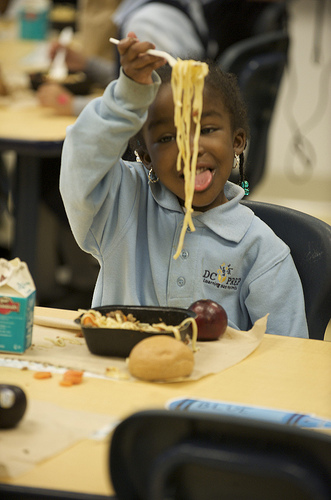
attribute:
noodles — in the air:
[165, 58, 212, 263]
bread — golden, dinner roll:
[123, 331, 200, 385]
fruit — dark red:
[187, 297, 228, 342]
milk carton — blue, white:
[1, 256, 38, 359]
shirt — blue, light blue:
[53, 60, 308, 342]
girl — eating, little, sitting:
[53, 34, 311, 342]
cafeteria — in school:
[2, 3, 328, 499]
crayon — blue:
[164, 398, 329, 435]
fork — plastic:
[109, 36, 209, 79]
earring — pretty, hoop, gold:
[144, 165, 162, 188]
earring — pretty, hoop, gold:
[228, 155, 241, 172]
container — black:
[70, 301, 198, 362]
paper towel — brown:
[3, 304, 271, 389]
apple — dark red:
[183, 295, 230, 342]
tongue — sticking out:
[190, 170, 215, 193]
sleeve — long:
[46, 66, 167, 260]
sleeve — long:
[246, 252, 309, 342]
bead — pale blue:
[239, 178, 249, 188]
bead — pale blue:
[240, 188, 251, 198]